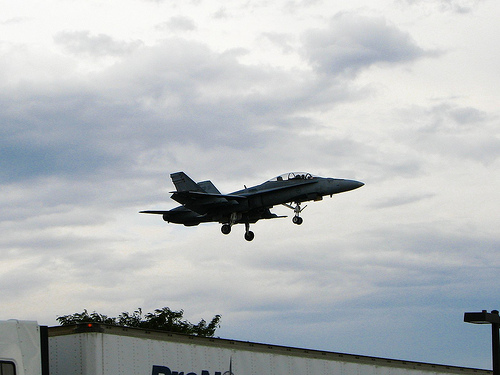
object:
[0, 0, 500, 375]
clouds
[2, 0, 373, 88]
sky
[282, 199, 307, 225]
landing gear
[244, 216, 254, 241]
landing gear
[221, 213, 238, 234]
landing gear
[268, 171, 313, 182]
cockpit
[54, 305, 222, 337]
tree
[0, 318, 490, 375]
truck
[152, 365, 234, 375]
writing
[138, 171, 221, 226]
tail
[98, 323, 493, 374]
side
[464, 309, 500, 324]
light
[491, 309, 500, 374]
light pole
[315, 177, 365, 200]
nose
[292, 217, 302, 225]
wheels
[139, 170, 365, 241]
jet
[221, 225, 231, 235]
wheels